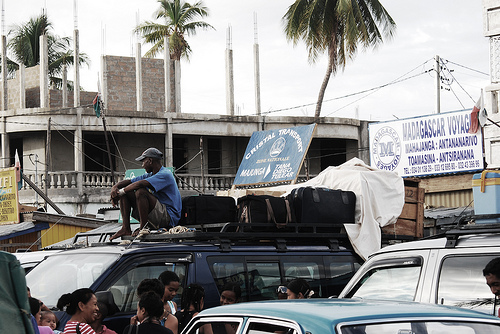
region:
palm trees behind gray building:
[0, 0, 401, 115]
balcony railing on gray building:
[4, 168, 321, 202]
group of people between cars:
[29, 268, 339, 333]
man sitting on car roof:
[108, 145, 188, 245]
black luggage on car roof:
[186, 175, 358, 242]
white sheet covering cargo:
[231, 156, 409, 253]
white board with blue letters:
[356, 105, 488, 177]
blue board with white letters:
[229, 120, 319, 185]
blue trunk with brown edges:
[468, 169, 499, 216]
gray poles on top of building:
[0, 32, 269, 117]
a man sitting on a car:
[108, 146, 185, 241]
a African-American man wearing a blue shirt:
[107, 144, 185, 238]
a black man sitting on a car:
[100, 141, 189, 239]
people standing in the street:
[54, 265, 321, 332]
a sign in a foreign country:
[356, 106, 496, 180]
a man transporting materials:
[110, 149, 374, 245]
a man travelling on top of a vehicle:
[29, 145, 365, 286]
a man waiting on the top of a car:
[97, 141, 189, 233]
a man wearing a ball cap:
[107, 146, 189, 238]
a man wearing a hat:
[102, 145, 185, 237]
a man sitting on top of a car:
[81, 134, 188, 284]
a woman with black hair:
[36, 282, 104, 331]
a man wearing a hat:
[139, 144, 170, 173]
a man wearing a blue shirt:
[142, 162, 185, 219]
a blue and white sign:
[356, 107, 480, 184]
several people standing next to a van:
[62, 274, 322, 332]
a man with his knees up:
[103, 150, 170, 247]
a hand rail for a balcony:
[33, 169, 237, 201]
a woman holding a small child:
[35, 307, 58, 332]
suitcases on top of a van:
[180, 184, 374, 242]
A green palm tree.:
[132, 0, 217, 62]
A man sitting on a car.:
[108, 150, 185, 240]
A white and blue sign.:
[366, 108, 487, 175]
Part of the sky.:
[420, 11, 470, 45]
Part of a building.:
[24, 110, 108, 204]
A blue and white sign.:
[236, 120, 316, 189]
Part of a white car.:
[341, 231, 498, 315]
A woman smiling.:
[58, 290, 102, 332]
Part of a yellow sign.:
[1, 167, 18, 224]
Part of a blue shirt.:
[158, 176, 173, 194]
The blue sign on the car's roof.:
[241, 129, 307, 189]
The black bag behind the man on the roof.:
[179, 195, 231, 219]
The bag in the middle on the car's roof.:
[240, 195, 295, 222]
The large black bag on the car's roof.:
[291, 184, 355, 216]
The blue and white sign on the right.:
[358, 115, 484, 167]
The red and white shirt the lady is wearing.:
[64, 322, 94, 332]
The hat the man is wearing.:
[131, 145, 163, 159]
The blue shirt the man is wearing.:
[137, 171, 182, 218]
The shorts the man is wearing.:
[149, 201, 171, 224]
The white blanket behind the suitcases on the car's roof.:
[277, 155, 408, 254]